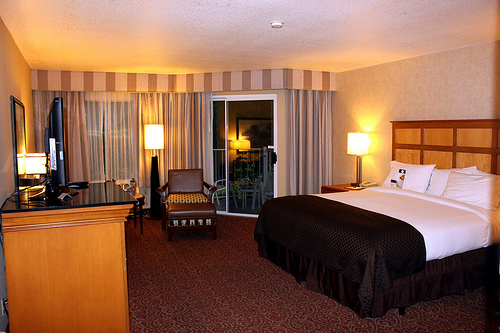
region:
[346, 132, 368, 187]
a table lamp with shade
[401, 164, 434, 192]
a white bed pillow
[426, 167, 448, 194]
a white bed pillow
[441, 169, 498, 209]
a white bed pillow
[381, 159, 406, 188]
a white bed pillow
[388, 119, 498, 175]
a brown wood headboard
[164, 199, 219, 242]
a leather ottoman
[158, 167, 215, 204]
a brown leader side chair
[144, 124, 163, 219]
a floor lamp with shade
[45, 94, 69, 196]
a black flat screen TV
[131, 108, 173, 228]
light in the room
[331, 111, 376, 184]
lamp on the desk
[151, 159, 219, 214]
chair in the room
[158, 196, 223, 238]
rest in front of chair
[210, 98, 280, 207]
door made of glass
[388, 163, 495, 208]
pillows on the bed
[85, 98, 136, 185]
curtains that are closed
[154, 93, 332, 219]
curtains that are open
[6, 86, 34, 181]
image on the wall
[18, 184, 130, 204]
surface on the furniture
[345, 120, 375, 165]
light on a table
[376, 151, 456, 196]
pillow on a bed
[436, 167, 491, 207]
pillow on a bed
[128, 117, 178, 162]
lamp next to a window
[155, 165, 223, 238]
chair near a window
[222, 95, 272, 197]
door near a window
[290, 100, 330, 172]
curtain on a window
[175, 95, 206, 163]
curtain on a door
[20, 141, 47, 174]
lamp in a room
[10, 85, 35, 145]
picture on a wall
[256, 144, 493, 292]
A bed in the room.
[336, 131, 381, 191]
A lamp on the table.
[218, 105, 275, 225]
A door to the patio.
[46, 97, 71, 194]
Television on the dresser.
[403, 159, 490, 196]
Pillows on the bed.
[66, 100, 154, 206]
Curtains on the window.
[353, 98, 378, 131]
The light shining on the wall.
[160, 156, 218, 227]
A chair by the sliding glass door.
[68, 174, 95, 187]
Remote control on the dresser.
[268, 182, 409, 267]
The bedspread is brown.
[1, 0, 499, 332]
A room in a hotel.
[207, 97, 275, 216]
A glass door that leads out to a patio.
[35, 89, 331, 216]
Brown drapes for the door and window.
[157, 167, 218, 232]
A red and white chair.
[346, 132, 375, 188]
A lamp with a white lampshade.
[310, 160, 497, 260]
White sheets and pillowcases.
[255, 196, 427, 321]
Brown blanket across the bottom of the bed.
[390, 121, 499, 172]
A light and dark wood headboard.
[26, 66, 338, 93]
A long striped valance over the door and window.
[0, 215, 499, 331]
Brown carpet on the floor.